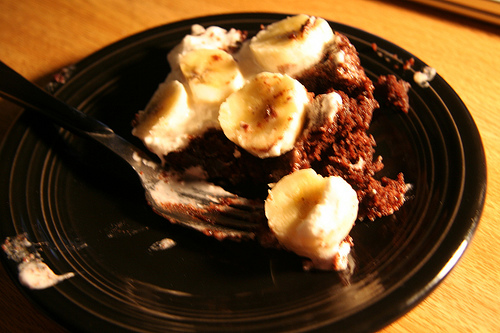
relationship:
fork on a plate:
[1, 61, 275, 242] [2, 11, 486, 330]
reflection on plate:
[323, 268, 387, 318] [2, 11, 486, 330]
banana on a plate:
[220, 75, 317, 162] [47, 39, 302, 307]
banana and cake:
[220, 75, 317, 162] [296, 83, 406, 196]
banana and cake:
[135, 73, 194, 162] [291, 31, 411, 220]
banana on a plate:
[135, 73, 194, 162] [2, 11, 486, 330]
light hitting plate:
[331, 267, 410, 323] [7, 75, 268, 322]